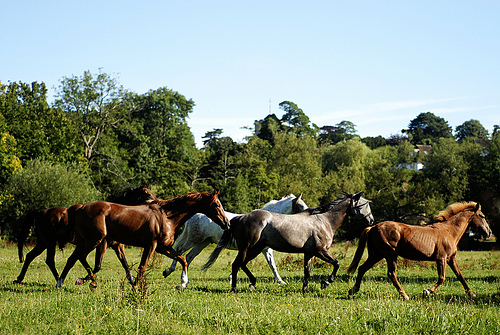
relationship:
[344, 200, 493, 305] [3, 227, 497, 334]
horse in a field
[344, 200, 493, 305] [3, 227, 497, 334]
horse in field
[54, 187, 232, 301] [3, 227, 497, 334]
horse in field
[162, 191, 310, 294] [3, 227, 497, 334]
horse in field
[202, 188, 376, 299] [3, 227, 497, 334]
horse in field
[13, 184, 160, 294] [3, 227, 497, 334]
horse in field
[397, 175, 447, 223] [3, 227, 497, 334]
tree next to field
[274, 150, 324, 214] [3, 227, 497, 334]
tree next to field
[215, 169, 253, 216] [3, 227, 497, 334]
tree next to field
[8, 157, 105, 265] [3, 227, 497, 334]
tree next to field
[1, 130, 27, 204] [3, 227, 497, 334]
tree next to field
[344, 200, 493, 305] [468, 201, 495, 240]
horse has head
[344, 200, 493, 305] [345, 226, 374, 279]
horse has tail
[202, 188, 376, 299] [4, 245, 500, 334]
horse on grass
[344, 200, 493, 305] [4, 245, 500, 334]
horse on grass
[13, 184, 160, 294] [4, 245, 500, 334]
horse on grass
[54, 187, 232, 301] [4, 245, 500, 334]
horse on grass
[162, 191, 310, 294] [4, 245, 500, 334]
horse on grass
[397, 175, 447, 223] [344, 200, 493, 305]
tree behind horse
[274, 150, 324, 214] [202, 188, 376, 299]
tree behind horse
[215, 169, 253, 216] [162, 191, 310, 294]
tree behind horse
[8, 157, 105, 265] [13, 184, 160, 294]
tree behind horse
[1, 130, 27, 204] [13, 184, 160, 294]
tree behind horse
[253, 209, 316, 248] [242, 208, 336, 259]
sheen on body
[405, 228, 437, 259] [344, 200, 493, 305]
ribs are on horse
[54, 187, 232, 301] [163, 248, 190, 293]
horse has leg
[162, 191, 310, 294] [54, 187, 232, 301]
horse behind horse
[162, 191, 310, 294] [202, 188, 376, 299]
horse behind horse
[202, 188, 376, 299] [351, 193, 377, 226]
horse wears head covering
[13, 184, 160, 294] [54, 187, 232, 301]
horse behind horse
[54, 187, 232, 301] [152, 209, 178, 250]
horse has muscles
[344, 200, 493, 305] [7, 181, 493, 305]
horse in group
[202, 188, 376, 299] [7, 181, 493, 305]
horse in group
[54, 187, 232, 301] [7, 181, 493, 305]
horse in group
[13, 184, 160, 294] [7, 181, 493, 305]
horse in group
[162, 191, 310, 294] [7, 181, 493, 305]
horse in group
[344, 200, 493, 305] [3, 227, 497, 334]
horse runs in field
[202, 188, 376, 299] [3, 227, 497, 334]
horse runs in field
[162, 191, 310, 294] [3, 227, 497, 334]
horse runs in field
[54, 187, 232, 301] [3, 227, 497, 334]
horse runs in field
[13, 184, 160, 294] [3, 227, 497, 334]
horse runs in field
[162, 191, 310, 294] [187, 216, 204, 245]
horse has spots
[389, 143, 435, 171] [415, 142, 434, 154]
house has roof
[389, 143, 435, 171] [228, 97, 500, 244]
house surrounded by trees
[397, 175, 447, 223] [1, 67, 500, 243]
tree in a row of trees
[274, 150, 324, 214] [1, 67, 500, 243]
tree in a row of trees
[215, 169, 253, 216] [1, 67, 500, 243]
tree in a row of trees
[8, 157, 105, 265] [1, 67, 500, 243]
tree in a row of trees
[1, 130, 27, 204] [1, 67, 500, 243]
tree in a row of trees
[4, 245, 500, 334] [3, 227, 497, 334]
grass in field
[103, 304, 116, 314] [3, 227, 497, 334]
flower in field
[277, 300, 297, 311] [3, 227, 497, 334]
flower in field